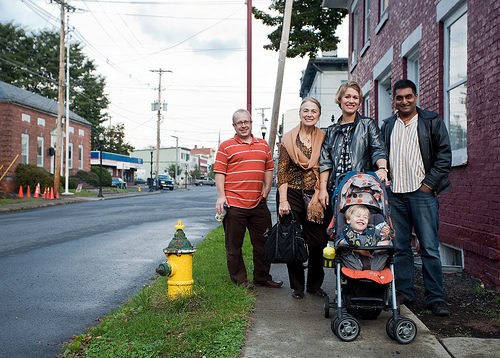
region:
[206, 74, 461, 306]
People standing on the sidewalk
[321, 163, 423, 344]
The boy is sitting in the stroller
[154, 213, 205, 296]
The fire hydrant is green and yellow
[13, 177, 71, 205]
A cluster of orange cones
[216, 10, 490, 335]
They are standing by a brick building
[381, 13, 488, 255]
The brick is red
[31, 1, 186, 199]
Tall brown power lines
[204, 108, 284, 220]
The man is wearing a striped shirt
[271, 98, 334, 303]
The woman is holding a black bag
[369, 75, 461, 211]
The man has a black jacket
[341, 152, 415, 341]
a baby in a stroller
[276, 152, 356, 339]
a baby in a stroller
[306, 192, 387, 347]
a baby in a stroller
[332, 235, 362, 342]
a baby in a stroller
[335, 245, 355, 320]
a baby in a stroller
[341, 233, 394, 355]
a baby in a stroller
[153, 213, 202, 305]
a yellow fire hydrant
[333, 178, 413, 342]
a toddler in a stroller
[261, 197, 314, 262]
woman holding a black bag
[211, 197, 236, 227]
man holding a bottle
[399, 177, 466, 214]
man with his hand in his pocket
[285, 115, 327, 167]
woman with a brown scarf around her neck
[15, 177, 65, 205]
a bunch of orange traffic cones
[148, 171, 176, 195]
a black truck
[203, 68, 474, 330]
four people standing on a sidewalk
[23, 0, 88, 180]
a telephone pole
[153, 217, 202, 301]
a yellow and green fire hydrant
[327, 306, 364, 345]
the wheel of a stroller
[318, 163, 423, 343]
a baby stroller on the sidewalk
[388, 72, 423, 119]
the head of a man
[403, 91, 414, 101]
the eye of a man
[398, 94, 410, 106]
the nose of a man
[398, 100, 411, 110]
the mouth of a man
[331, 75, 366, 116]
the head of a woman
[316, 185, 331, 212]
the hand of a woman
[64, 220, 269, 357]
a patch of green grass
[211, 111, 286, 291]
man standing on grass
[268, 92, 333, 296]
woman standing on sidewalk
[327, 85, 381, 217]
woman standing on sidewalk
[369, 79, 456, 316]
man standing in grass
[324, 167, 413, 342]
a child in a stroller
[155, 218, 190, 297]
a yellow green fire hydrant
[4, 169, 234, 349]
a paved city street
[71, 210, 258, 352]
a strip of green grass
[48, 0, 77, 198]
a tall telephone pole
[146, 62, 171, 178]
a tall telephone pole